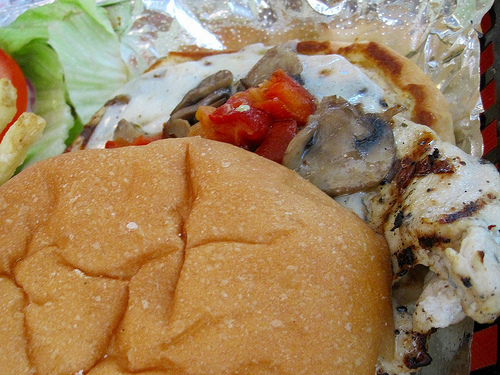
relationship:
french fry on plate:
[3, 72, 52, 178] [7, 7, 481, 374]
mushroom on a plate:
[282, 95, 408, 196] [448, 0, 497, 371]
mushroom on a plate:
[162, 65, 235, 133] [448, 0, 497, 371]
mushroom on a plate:
[231, 42, 306, 94] [448, 0, 497, 371]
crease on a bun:
[177, 145, 207, 297] [3, 135, 395, 372]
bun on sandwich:
[121, 169, 278, 267] [22, 57, 399, 302]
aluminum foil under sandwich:
[0, 0, 499, 159] [0, 140, 452, 370]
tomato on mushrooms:
[196, 69, 319, 164] [311, 126, 372, 174]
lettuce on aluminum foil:
[2, 0, 154, 181] [0, 0, 499, 159]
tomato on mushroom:
[195, 67, 319, 162] [282, 95, 404, 195]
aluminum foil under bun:
[0, 0, 499, 159] [199, 230, 323, 305]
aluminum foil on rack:
[0, 0, 499, 159] [482, 31, 498, 161]